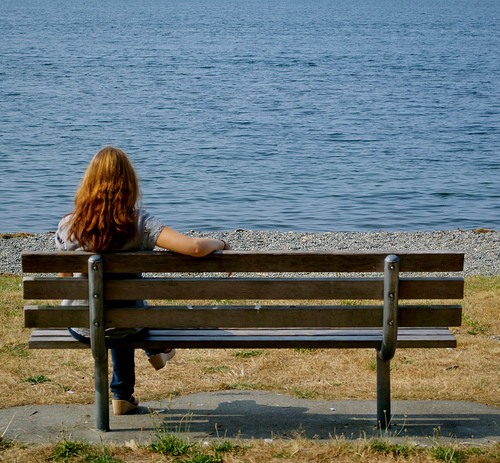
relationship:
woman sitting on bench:
[54, 148, 235, 415] [20, 250, 463, 432]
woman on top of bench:
[54, 148, 235, 415] [20, 250, 463, 432]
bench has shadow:
[20, 250, 463, 432] [110, 401, 498, 440]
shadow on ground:
[110, 401, 498, 440] [2, 230, 499, 461]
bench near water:
[20, 250, 463, 432] [2, 3, 496, 235]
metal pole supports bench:
[376, 352, 391, 428] [20, 250, 463, 432]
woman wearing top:
[54, 148, 235, 415] [54, 207, 161, 336]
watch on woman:
[220, 238, 229, 247] [54, 148, 235, 415]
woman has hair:
[54, 148, 235, 415] [69, 146, 140, 244]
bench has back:
[20, 250, 463, 432] [20, 251, 462, 327]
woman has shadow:
[54, 148, 235, 415] [110, 401, 498, 440]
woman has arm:
[54, 148, 235, 415] [147, 217, 238, 281]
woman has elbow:
[54, 148, 235, 415] [189, 235, 210, 260]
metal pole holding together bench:
[88, 254, 109, 435] [20, 250, 463, 432]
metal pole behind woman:
[376, 352, 391, 428] [54, 148, 235, 415]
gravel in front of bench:
[2, 229, 499, 281] [20, 250, 463, 432]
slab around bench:
[0, 383, 500, 449] [20, 250, 463, 432]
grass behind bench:
[2, 270, 499, 460] [20, 250, 463, 432]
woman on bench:
[54, 148, 235, 415] [20, 250, 463, 432]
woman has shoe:
[54, 148, 235, 415] [112, 397, 141, 416]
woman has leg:
[54, 148, 235, 415] [109, 348, 143, 412]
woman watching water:
[54, 148, 235, 415] [2, 3, 496, 235]